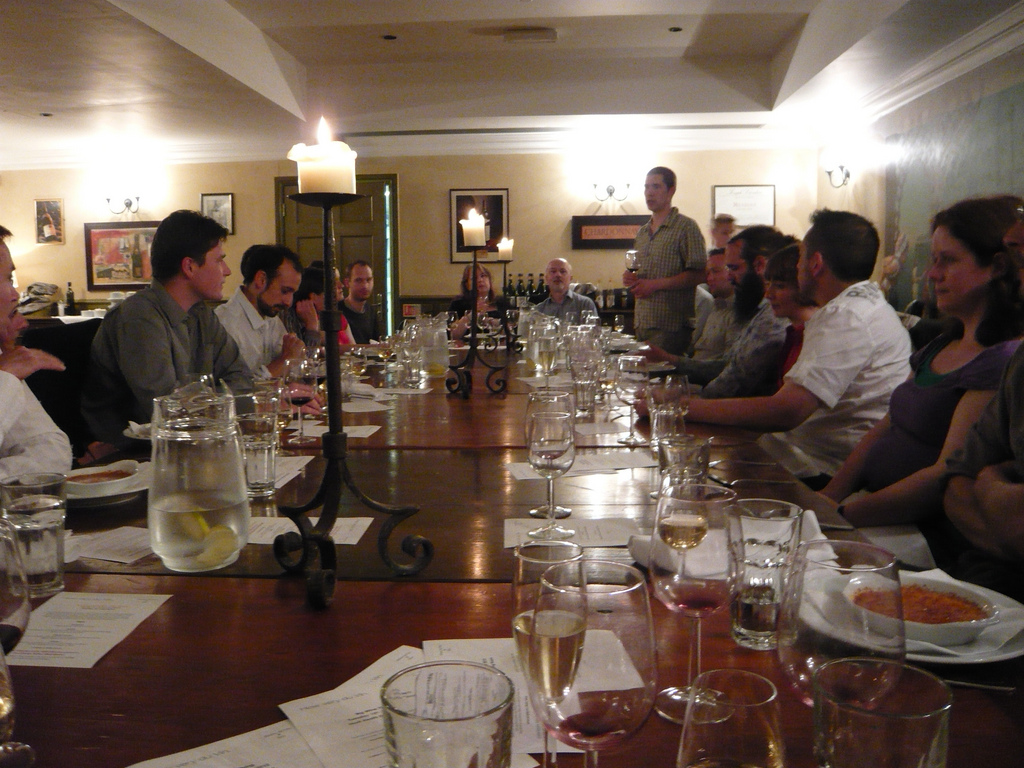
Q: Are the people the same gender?
A: No, they are both male and female.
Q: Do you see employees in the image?
A: No, there are no employees.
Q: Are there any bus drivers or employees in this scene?
A: No, there are no employees or bus drivers.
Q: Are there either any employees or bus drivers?
A: No, there are no employees or bus drivers.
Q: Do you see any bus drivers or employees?
A: No, there are no employees or bus drivers.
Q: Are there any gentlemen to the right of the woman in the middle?
A: Yes, there is a gentleman to the right of the woman.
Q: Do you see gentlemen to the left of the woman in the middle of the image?
A: No, the gentleman is to the right of the woman.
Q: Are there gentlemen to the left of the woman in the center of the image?
A: No, the gentleman is to the right of the woman.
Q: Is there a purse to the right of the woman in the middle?
A: No, there is a gentleman to the right of the woman.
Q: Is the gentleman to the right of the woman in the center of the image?
A: Yes, the gentleman is to the right of the woman.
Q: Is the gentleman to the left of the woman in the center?
A: No, the gentleman is to the right of the woman.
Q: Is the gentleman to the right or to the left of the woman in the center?
A: The gentleman is to the right of the woman.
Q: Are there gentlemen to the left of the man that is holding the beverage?
A: Yes, there is a gentleman to the left of the man.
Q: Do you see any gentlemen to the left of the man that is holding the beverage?
A: Yes, there is a gentleman to the left of the man.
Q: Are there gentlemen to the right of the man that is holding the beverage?
A: No, the gentleman is to the left of the man.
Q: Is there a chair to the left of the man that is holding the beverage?
A: No, there is a gentleman to the left of the man.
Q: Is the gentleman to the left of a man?
A: Yes, the gentleman is to the left of a man.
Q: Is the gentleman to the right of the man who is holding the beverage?
A: No, the gentleman is to the left of the man.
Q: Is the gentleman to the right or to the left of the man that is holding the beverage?
A: The gentleman is to the left of the man.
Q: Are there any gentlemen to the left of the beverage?
A: Yes, there is a gentleman to the left of the beverage.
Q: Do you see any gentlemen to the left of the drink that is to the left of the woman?
A: Yes, there is a gentleman to the left of the beverage.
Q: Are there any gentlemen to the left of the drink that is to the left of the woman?
A: Yes, there is a gentleman to the left of the beverage.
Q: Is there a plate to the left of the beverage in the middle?
A: No, there is a gentleman to the left of the beverage.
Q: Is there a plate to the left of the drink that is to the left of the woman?
A: No, there is a gentleman to the left of the beverage.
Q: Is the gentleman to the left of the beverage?
A: Yes, the gentleman is to the left of the beverage.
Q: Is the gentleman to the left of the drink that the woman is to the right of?
A: Yes, the gentleman is to the left of the beverage.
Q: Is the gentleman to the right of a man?
A: No, the gentleman is to the left of a man.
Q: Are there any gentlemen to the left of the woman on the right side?
A: Yes, there is a gentleman to the left of the woman.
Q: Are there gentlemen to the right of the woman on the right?
A: No, the gentleman is to the left of the woman.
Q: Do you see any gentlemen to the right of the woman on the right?
A: No, the gentleman is to the left of the woman.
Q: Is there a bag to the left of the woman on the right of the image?
A: No, there is a gentleman to the left of the woman.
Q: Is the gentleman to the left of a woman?
A: Yes, the gentleman is to the left of a woman.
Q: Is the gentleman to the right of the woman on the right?
A: No, the gentleman is to the left of the woman.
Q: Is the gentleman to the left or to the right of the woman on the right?
A: The gentleman is to the left of the woman.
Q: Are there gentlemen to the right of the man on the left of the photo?
A: Yes, there is a gentleman to the right of the man.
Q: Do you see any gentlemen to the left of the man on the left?
A: No, the gentleman is to the right of the man.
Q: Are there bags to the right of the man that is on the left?
A: No, there is a gentleman to the right of the man.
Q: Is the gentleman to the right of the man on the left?
A: Yes, the gentleman is to the right of the man.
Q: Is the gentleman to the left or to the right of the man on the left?
A: The gentleman is to the right of the man.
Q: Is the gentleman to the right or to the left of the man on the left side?
A: The gentleman is to the right of the man.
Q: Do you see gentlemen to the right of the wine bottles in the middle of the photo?
A: Yes, there is a gentleman to the right of the wine bottles.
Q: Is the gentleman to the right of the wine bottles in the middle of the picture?
A: Yes, the gentleman is to the right of the wine bottles.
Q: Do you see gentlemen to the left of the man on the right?
A: Yes, there is a gentleman to the left of the man.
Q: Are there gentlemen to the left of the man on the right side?
A: Yes, there is a gentleman to the left of the man.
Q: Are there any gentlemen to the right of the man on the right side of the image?
A: No, the gentleman is to the left of the man.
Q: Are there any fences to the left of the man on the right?
A: No, there is a gentleman to the left of the man.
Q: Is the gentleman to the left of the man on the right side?
A: Yes, the gentleman is to the left of the man.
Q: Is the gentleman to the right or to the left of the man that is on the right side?
A: The gentleman is to the left of the man.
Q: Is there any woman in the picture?
A: Yes, there is a woman.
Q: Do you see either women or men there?
A: Yes, there is a woman.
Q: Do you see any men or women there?
A: Yes, there is a woman.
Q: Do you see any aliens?
A: No, there are no aliens.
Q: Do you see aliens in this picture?
A: No, there are no aliens.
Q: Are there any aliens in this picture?
A: No, there are no aliens.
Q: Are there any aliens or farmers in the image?
A: No, there are no aliens or farmers.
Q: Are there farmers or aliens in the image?
A: No, there are no aliens or farmers.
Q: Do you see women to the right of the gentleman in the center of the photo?
A: Yes, there is a woman to the right of the gentleman.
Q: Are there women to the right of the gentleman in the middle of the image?
A: Yes, there is a woman to the right of the gentleman.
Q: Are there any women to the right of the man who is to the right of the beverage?
A: Yes, there is a woman to the right of the man.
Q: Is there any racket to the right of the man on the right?
A: No, there is a woman to the right of the man.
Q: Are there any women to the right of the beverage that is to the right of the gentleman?
A: Yes, there is a woman to the right of the beverage.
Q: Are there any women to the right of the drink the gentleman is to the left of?
A: Yes, there is a woman to the right of the beverage.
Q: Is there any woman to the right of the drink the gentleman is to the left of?
A: Yes, there is a woman to the right of the beverage.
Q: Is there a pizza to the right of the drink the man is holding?
A: No, there is a woman to the right of the beverage.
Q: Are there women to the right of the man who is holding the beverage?
A: Yes, there is a woman to the right of the man.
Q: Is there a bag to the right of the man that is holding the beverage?
A: No, there is a woman to the right of the man.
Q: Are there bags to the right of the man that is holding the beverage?
A: No, there is a woman to the right of the man.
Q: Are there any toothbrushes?
A: No, there are no toothbrushes.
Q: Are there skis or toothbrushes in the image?
A: No, there are no toothbrushes or skis.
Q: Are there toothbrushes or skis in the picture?
A: No, there are no toothbrushes or skis.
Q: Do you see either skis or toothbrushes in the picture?
A: No, there are no toothbrushes or skis.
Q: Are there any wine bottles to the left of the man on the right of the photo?
A: Yes, there are wine bottles to the left of the man.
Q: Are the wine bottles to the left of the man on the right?
A: Yes, the wine bottles are to the left of the man.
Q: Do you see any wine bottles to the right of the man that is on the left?
A: Yes, there are wine bottles to the right of the man.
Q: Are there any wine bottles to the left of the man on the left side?
A: No, the wine bottles are to the right of the man.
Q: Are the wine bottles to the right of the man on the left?
A: Yes, the wine bottles are to the right of the man.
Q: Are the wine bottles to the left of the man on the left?
A: No, the wine bottles are to the right of the man.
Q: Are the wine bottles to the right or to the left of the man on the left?
A: The wine bottles are to the right of the man.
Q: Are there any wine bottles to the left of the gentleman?
A: Yes, there are wine bottles to the left of the gentleman.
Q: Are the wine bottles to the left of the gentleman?
A: Yes, the wine bottles are to the left of the gentleman.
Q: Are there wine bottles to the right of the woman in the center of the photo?
A: Yes, there are wine bottles to the right of the woman.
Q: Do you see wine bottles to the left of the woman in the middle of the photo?
A: No, the wine bottles are to the right of the woman.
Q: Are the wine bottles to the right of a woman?
A: Yes, the wine bottles are to the right of a woman.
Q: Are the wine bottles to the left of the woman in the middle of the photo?
A: No, the wine bottles are to the right of the woman.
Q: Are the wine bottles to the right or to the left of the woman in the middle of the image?
A: The wine bottles are to the right of the woman.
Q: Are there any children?
A: No, there are no children.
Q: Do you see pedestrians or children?
A: No, there are no children or pedestrians.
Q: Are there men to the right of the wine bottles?
A: Yes, there is a man to the right of the wine bottles.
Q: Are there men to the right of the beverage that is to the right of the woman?
A: Yes, there is a man to the right of the beverage.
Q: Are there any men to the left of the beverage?
A: No, the man is to the right of the beverage.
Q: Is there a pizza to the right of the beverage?
A: No, there is a man to the right of the beverage.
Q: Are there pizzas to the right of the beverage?
A: No, there is a man to the right of the beverage.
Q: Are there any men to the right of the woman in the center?
A: Yes, there is a man to the right of the woman.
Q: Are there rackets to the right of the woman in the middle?
A: No, there is a man to the right of the woman.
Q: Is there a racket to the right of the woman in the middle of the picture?
A: No, there is a man to the right of the woman.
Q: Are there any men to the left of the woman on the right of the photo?
A: Yes, there is a man to the left of the woman.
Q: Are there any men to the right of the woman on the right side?
A: No, the man is to the left of the woman.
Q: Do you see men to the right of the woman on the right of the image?
A: No, the man is to the left of the woman.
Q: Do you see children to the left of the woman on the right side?
A: No, there is a man to the left of the woman.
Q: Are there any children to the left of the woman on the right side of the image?
A: No, there is a man to the left of the woman.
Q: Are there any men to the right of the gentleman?
A: Yes, there is a man to the right of the gentleman.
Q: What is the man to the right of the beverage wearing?
A: The man is wearing a shirt.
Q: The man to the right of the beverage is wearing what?
A: The man is wearing a shirt.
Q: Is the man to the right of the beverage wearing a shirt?
A: Yes, the man is wearing a shirt.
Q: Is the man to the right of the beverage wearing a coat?
A: No, the man is wearing a shirt.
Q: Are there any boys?
A: No, there are no boys.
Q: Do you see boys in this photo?
A: No, there are no boys.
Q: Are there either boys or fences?
A: No, there are no boys or fences.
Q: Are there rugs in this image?
A: No, there are no rugs.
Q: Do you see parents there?
A: No, there are no parents.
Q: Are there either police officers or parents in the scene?
A: No, there are no parents or police officers.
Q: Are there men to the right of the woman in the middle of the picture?
A: Yes, there is a man to the right of the woman.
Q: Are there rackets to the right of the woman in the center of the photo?
A: No, there is a man to the right of the woman.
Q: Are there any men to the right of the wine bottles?
A: Yes, there is a man to the right of the wine bottles.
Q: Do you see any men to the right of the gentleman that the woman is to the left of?
A: Yes, there is a man to the right of the gentleman.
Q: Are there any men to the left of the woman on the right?
A: Yes, there is a man to the left of the woman.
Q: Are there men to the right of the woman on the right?
A: No, the man is to the left of the woman.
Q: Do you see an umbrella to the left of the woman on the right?
A: No, there is a man to the left of the woman.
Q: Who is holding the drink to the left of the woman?
A: The man is holding the beverage.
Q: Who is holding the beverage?
A: The man is holding the beverage.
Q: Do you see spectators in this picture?
A: No, there are no spectators.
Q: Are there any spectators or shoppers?
A: No, there are no spectators or shoppers.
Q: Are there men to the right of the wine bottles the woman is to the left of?
A: Yes, there is a man to the right of the wine bottles.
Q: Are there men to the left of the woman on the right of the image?
A: Yes, there is a man to the left of the woman.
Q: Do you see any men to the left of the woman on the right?
A: Yes, there is a man to the left of the woman.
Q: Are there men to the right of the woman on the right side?
A: No, the man is to the left of the woman.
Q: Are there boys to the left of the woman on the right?
A: No, there is a man to the left of the woman.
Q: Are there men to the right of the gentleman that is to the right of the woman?
A: Yes, there is a man to the right of the gentleman.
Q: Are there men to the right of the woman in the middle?
A: Yes, there is a man to the right of the woman.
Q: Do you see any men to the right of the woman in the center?
A: Yes, there is a man to the right of the woman.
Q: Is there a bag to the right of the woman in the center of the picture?
A: No, there is a man to the right of the woman.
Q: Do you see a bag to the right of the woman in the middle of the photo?
A: No, there is a man to the right of the woman.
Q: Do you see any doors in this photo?
A: Yes, there is a door.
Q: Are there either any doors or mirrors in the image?
A: Yes, there is a door.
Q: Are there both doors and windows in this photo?
A: No, there is a door but no windows.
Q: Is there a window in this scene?
A: No, there are no windows.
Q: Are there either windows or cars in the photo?
A: No, there are no windows or cars.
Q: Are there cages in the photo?
A: No, there are no cages.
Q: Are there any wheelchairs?
A: No, there are no wheelchairs.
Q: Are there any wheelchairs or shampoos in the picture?
A: No, there are no wheelchairs or shampoos.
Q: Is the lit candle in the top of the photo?
A: Yes, the candle is in the top of the image.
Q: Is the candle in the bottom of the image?
A: No, the candle is in the top of the image.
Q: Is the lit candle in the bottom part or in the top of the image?
A: The candle is in the top of the image.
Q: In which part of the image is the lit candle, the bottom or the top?
A: The candle is in the top of the image.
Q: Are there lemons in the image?
A: Yes, there are lemons.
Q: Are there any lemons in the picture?
A: Yes, there are lemons.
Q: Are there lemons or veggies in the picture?
A: Yes, there are lemons.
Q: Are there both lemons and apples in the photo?
A: No, there are lemons but no apples.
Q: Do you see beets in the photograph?
A: No, there are no beets.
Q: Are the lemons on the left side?
A: Yes, the lemons are on the left of the image.